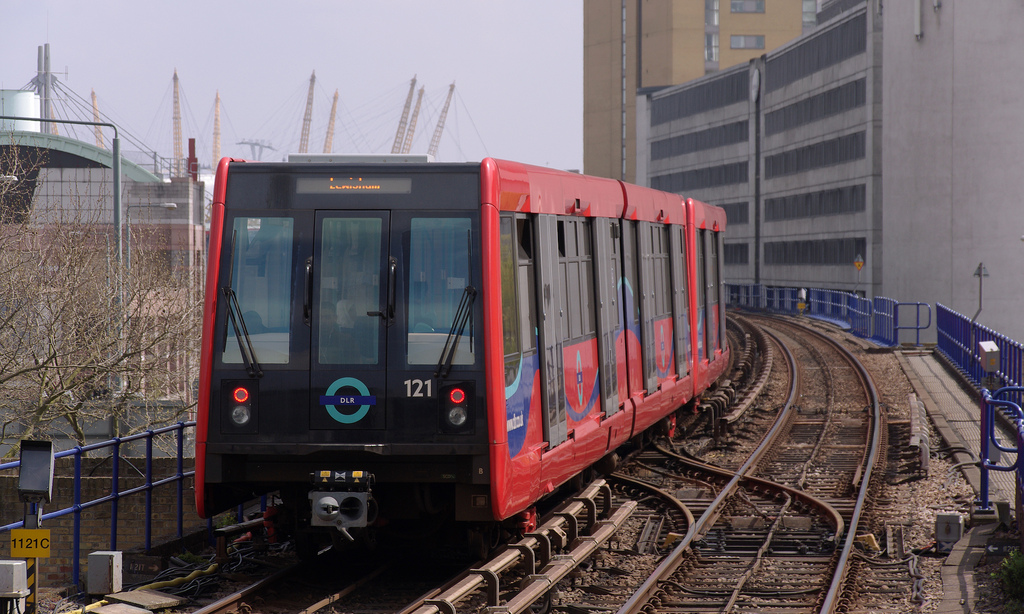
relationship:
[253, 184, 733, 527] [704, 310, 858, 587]
train on tracks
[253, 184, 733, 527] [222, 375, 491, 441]
train has lights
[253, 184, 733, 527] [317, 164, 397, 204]
train has destination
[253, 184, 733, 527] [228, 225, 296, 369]
train has window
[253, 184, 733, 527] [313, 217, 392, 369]
train has window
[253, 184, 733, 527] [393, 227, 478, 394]
train has window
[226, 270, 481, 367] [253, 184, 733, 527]
wipers on train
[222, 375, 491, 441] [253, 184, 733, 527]
headlights on train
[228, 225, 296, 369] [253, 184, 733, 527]
window fronting train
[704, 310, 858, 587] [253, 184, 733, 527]
tracks under train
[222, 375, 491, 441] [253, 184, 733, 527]
lights fronting train